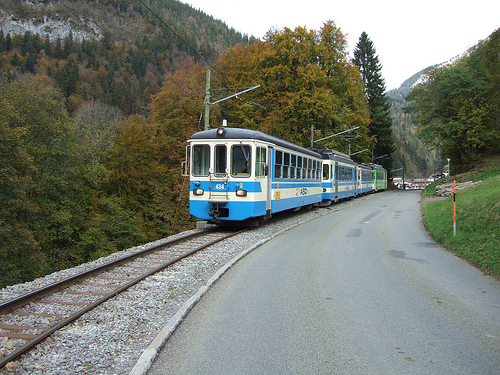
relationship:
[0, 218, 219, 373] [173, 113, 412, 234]
track under train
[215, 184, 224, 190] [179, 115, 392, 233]
number on front of train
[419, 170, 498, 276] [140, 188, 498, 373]
grass next to street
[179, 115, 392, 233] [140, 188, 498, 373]
train next to street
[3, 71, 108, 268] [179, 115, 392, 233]
tree next to train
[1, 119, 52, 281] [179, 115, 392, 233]
tree next to train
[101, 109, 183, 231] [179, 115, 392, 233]
tree next to train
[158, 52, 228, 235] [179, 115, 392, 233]
tree next to train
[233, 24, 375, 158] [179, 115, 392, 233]
tree next to train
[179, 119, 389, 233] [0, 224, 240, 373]
train on track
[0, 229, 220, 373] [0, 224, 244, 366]
gravel between tracks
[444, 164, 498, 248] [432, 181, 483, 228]
pole sticking out of grass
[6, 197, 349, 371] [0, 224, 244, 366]
gravel near tracks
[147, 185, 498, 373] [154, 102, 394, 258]
road near train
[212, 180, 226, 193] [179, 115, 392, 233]
number on train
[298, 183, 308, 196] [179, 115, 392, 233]
writing on side of train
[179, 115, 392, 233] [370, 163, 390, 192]
train has car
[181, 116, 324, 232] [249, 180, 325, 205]
train car has stripes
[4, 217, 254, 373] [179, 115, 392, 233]
tracks in front of train